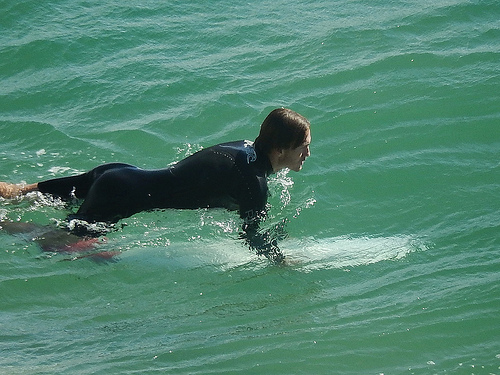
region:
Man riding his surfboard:
[25, 99, 460, 299]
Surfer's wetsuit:
[45, 142, 272, 229]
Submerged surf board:
[109, 217, 441, 297]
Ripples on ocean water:
[25, 25, 263, 143]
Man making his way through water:
[20, 135, 281, 260]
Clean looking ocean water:
[40, 286, 413, 371]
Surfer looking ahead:
[225, 96, 340, 231]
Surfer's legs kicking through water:
[7, 158, 164, 269]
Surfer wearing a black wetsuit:
[31, 106, 332, 244]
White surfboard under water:
[96, 210, 441, 300]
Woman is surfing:
[0, 90, 330, 300]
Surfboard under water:
[106, 225, 431, 280]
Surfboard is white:
[115, 220, 430, 290]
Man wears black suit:
[0, 93, 318, 299]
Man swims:
[7, 80, 327, 297]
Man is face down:
[0, 90, 325, 310]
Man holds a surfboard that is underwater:
[6, 79, 436, 314]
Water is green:
[0, 5, 496, 106]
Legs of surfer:
[0, 168, 45, 254]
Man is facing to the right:
[9, 90, 333, 305]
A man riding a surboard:
[1, 106, 431, 348]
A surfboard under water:
[91, 222, 441, 285]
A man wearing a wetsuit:
[20, 82, 371, 258]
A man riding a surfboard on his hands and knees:
[60, 107, 363, 312]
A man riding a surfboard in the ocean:
[6, 77, 438, 329]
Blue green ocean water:
[322, 27, 498, 179]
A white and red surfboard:
[75, 233, 470, 316]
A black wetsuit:
[33, 142, 268, 232]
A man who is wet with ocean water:
[62, 63, 341, 313]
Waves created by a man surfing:
[22, 142, 297, 249]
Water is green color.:
[315, 50, 447, 166]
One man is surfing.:
[83, 145, 234, 236]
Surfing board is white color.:
[302, 225, 397, 300]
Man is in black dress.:
[75, 140, 275, 230]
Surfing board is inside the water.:
[165, 221, 430, 291]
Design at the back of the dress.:
[230, 135, 255, 170]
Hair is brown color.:
[265, 115, 290, 135]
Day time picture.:
[30, 40, 455, 350]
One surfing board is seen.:
[310, 225, 435, 290]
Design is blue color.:
[212, 140, 258, 171]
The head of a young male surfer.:
[253, 104, 315, 175]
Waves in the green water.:
[54, 39, 310, 103]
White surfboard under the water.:
[43, 236, 421, 264]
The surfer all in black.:
[38, 131, 259, 263]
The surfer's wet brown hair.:
[260, 108, 310, 147]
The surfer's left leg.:
[2, 171, 39, 221]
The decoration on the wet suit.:
[219, 137, 256, 162]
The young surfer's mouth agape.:
[288, 155, 308, 172]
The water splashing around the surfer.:
[270, 176, 308, 213]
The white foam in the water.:
[48, 213, 117, 233]